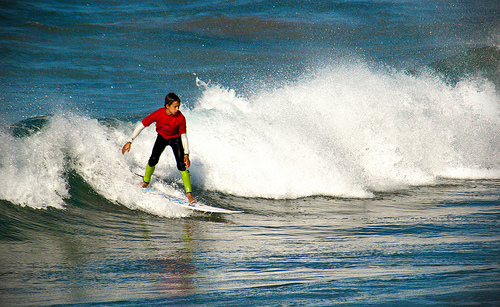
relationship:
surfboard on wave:
[107, 150, 257, 229] [5, 44, 499, 243]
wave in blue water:
[0, 36, 498, 228] [0, 1, 499, 306]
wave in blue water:
[0, 36, 498, 228] [224, 189, 450, 248]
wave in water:
[4, 63, 487, 210] [272, 225, 375, 286]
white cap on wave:
[2, 0, 498, 215] [257, 25, 437, 246]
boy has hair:
[120, 92, 196, 208] [163, 90, 183, 110]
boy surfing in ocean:
[118, 90, 203, 206] [77, 169, 465, 284]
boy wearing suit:
[120, 92, 196, 208] [125, 103, 205, 196]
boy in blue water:
[120, 92, 196, 208] [0, 1, 499, 306]